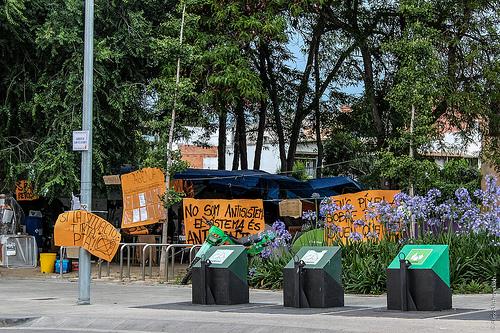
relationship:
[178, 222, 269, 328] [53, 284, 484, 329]
bucket on road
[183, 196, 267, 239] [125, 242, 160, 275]
sign on rack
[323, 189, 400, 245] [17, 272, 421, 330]
sign on road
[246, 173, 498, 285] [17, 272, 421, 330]
flowers on road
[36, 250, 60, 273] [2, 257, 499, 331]
bucket on ground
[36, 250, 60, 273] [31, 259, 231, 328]
bucket on road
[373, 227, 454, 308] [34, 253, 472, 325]
box on road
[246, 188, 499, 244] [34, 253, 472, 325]
flowers on road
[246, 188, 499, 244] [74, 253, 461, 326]
flowers on road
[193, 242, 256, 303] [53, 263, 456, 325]
bucket on road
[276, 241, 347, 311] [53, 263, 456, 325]
box on road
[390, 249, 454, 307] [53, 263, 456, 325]
box on road